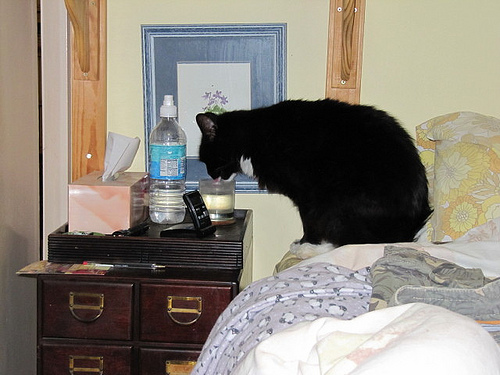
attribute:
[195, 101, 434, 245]
cat — black, drinking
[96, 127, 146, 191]
tissue — white, box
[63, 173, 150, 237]
box — orange, pink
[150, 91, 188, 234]
bottle — plastic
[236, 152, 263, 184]
patch — white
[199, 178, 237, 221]
glass — white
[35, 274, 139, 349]
drawer — wooden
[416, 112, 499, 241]
pillowcase — floral, yellow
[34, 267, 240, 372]
table — wooden, wood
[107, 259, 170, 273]
pen — black, ballpoint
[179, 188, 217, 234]
clock — black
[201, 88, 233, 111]
flower — purple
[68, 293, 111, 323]
pull — gold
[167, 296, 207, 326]
pull — gold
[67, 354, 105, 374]
pull — gold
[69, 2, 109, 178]
bracket — wooden